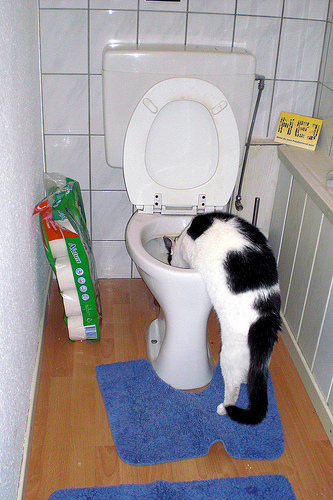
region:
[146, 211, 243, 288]
The cat is in the toilet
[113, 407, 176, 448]
The rug is blue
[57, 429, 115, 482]
The flooring is wooden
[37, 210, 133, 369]
The toilet paper is near the wall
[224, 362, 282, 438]
The cat's tail is black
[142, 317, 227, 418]
The toilet is connected to the floor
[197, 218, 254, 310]
The cat is black and white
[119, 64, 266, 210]
The seat is up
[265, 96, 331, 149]
The sign is yellow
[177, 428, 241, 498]
There are 2 rugs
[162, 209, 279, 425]
a cat with it's face in the toilet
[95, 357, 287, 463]
a blue bathroom mat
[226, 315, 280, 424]
a cat's fluffy tail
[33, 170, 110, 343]
a package of toilet paper rolls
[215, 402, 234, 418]
a cat's hind paw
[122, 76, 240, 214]
the lid of a toilet seat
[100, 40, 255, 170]
the tank of a toilet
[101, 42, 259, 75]
the lid of a toilet tank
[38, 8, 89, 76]
a rectangular shaped bathroom tile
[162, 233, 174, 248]
a cat's pointy ear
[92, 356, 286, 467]
blue toilet contour rug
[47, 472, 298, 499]
blue shag bathroom rug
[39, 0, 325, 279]
white tiled wall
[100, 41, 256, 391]
toilet with lid up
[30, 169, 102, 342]
unopened package of toilet tissue rolls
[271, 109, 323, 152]
yellow card with the initials HEJ on it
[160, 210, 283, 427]
black and white cat leaning into toilet bowl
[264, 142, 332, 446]
white painted wall boards with shelf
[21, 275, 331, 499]
wood design floor linoleum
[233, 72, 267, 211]
pipe plumbing attached to toilet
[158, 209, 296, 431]
black and white cat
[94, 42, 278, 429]
white toliet with cat in it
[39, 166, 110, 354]
pack of toilet paper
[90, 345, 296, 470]
blue toilet mat on floor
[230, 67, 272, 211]
metal pie on side of toilet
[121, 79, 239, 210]
toilet lid lifted up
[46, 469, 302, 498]
blue restroom mat on floor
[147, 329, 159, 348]
toilet screw on floor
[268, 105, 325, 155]
book on side of ledge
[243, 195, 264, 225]
handle of plunger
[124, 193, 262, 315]
cat crawling into a toilet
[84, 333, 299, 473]
blue carpeted toilet mat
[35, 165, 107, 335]
pack of rolls of toilet paper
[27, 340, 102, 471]
hardwood flooring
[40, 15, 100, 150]
wall tiles in a bathroom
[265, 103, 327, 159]
card on a ledge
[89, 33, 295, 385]
toilet being played with by a cat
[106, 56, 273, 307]
toilet with a lifted lid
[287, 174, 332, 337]
wood panels